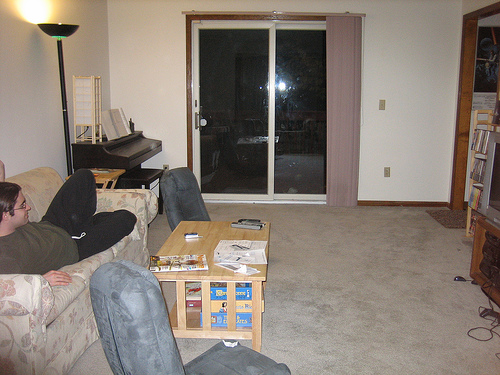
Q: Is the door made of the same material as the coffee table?
A: No, the door is made of glass and the coffee table is made of wood.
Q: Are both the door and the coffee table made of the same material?
A: No, the door is made of glass and the coffee table is made of wood.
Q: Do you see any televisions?
A: Yes, there is a television.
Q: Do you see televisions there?
A: Yes, there is a television.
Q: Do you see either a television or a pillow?
A: Yes, there is a television.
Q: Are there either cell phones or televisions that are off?
A: Yes, the television is off.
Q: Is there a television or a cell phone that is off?
A: Yes, the television is off.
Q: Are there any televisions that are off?
A: Yes, there is a television that is off.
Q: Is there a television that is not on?
A: Yes, there is a television that is off.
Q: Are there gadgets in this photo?
A: No, there are no gadgets.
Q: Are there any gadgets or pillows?
A: No, there are no gadgets or pillows.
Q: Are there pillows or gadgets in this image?
A: No, there are no gadgets or pillows.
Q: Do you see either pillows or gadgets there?
A: No, there are no gadgets or pillows.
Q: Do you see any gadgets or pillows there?
A: No, there are no gadgets or pillows.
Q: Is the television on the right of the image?
A: Yes, the television is on the right of the image.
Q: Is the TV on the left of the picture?
A: No, the TV is on the right of the image.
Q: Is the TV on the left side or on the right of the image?
A: The TV is on the right of the image.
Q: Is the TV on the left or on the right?
A: The TV is on the right of the image.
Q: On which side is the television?
A: The television is on the right of the image.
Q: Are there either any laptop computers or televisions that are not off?
A: No, there is a television but it is off.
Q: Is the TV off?
A: Yes, the TV is off.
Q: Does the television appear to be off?
A: Yes, the television is off.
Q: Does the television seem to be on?
A: No, the television is off.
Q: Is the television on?
A: No, the television is off.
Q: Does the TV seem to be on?
A: No, the TV is off.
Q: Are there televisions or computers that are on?
A: No, there is a television but it is off.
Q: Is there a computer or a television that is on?
A: No, there is a television but it is off.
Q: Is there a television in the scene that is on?
A: No, there is a television but it is off.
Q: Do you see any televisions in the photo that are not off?
A: No, there is a television but it is off.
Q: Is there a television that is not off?
A: No, there is a television but it is off.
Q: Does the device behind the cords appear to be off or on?
A: The TV is off.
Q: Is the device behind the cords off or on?
A: The TV is off.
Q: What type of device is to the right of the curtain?
A: The device is a television.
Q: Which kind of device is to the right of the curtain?
A: The device is a television.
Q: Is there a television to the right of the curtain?
A: Yes, there is a television to the right of the curtain.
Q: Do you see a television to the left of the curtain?
A: No, the television is to the right of the curtain.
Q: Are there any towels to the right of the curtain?
A: No, there is a television to the right of the curtain.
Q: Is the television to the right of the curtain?
A: Yes, the television is to the right of the curtain.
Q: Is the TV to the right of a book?
A: No, the TV is to the right of the curtain.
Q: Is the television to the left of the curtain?
A: No, the television is to the right of the curtain.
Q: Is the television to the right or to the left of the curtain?
A: The television is to the right of the curtain.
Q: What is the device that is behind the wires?
A: The device is a television.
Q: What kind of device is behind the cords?
A: The device is a television.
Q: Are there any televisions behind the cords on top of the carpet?
A: Yes, there is a television behind the wires.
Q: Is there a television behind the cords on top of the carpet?
A: Yes, there is a television behind the wires.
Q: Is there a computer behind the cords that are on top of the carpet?
A: No, there is a television behind the cords.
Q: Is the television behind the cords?
A: Yes, the television is behind the cords.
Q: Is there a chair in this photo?
A: Yes, there is a chair.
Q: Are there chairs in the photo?
A: Yes, there is a chair.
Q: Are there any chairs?
A: Yes, there is a chair.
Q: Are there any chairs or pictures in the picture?
A: Yes, there is a chair.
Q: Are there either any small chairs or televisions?
A: Yes, there is a small chair.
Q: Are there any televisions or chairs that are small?
A: Yes, the chair is small.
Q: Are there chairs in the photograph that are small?
A: Yes, there is a small chair.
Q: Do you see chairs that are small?
A: Yes, there is a chair that is small.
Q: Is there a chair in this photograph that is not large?
A: Yes, there is a small chair.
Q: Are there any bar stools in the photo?
A: No, there are no bar stools.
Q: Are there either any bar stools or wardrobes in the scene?
A: No, there are no bar stools or wardrobes.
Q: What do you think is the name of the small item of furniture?
A: The piece of furniture is a chair.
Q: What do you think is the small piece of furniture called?
A: The piece of furniture is a chair.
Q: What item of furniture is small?
A: The piece of furniture is a chair.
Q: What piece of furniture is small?
A: The piece of furniture is a chair.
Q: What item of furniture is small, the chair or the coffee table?
A: The chair is small.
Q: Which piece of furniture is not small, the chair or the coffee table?
A: The coffee table is not small.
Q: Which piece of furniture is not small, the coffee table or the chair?
A: The coffee table is not small.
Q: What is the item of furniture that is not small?
A: The piece of furniture is a coffee table.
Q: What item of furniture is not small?
A: The piece of furniture is a coffee table.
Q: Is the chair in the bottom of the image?
A: Yes, the chair is in the bottom of the image.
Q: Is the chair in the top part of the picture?
A: No, the chair is in the bottom of the image.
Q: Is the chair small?
A: Yes, the chair is small.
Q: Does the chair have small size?
A: Yes, the chair is small.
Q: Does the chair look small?
A: Yes, the chair is small.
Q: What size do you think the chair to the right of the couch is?
A: The chair is small.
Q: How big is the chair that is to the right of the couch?
A: The chair is small.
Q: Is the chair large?
A: No, the chair is small.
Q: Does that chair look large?
A: No, the chair is small.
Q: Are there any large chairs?
A: No, there is a chair but it is small.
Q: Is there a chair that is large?
A: No, there is a chair but it is small.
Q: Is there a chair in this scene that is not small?
A: No, there is a chair but it is small.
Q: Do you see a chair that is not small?
A: No, there is a chair but it is small.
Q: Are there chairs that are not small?
A: No, there is a chair but it is small.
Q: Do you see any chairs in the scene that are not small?
A: No, there is a chair but it is small.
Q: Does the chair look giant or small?
A: The chair is small.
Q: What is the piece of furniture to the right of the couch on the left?
A: The piece of furniture is a chair.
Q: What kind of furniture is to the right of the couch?
A: The piece of furniture is a chair.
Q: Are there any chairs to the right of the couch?
A: Yes, there is a chair to the right of the couch.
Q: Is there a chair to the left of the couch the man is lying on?
A: No, the chair is to the right of the couch.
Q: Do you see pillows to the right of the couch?
A: No, there is a chair to the right of the couch.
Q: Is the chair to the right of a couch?
A: Yes, the chair is to the right of a couch.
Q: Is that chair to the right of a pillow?
A: No, the chair is to the right of a couch.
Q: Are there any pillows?
A: No, there are no pillows.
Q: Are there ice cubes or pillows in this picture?
A: No, there are no pillows or ice cubes.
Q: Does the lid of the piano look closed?
A: Yes, the lid is closed.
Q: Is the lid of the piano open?
A: No, the lid is closed.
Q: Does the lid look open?
A: No, the lid is closed.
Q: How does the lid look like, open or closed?
A: The lid is closed.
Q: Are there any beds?
A: No, there are no beds.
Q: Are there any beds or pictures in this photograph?
A: No, there are no beds or pictures.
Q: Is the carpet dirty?
A: Yes, the carpet is dirty.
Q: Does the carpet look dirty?
A: Yes, the carpet is dirty.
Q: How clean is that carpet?
A: The carpet is dirty.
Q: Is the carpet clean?
A: No, the carpet is dirty.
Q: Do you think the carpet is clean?
A: No, the carpet is dirty.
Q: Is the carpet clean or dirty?
A: The carpet is dirty.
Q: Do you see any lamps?
A: Yes, there is a lamp.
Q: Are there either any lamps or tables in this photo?
A: Yes, there is a lamp.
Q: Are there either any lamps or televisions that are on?
A: Yes, the lamp is on.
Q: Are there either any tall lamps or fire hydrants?
A: Yes, there is a tall lamp.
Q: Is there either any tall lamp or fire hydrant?
A: Yes, there is a tall lamp.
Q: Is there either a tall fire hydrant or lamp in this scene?
A: Yes, there is a tall lamp.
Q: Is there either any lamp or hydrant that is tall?
A: Yes, the lamp is tall.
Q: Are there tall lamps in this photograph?
A: Yes, there is a tall lamp.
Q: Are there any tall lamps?
A: Yes, there is a tall lamp.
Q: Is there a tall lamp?
A: Yes, there is a tall lamp.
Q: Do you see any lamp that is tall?
A: Yes, there is a tall lamp.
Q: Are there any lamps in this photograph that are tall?
A: Yes, there is a lamp that is tall.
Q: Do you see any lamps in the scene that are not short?
A: Yes, there is a tall lamp.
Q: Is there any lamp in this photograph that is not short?
A: Yes, there is a tall lamp.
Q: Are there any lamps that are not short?
A: Yes, there is a tall lamp.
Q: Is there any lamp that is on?
A: Yes, there is a lamp that is on.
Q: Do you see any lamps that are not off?
A: Yes, there is a lamp that is on .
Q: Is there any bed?
A: No, there are no beds.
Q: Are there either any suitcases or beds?
A: No, there are no beds or suitcases.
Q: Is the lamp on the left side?
A: Yes, the lamp is on the left of the image.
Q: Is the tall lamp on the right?
A: No, the lamp is on the left of the image.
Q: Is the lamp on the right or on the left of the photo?
A: The lamp is on the left of the image.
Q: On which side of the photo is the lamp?
A: The lamp is on the left of the image.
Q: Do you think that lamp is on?
A: Yes, the lamp is on.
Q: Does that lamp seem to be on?
A: Yes, the lamp is on.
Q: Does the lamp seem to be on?
A: Yes, the lamp is on.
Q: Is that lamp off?
A: No, the lamp is on.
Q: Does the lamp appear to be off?
A: No, the lamp is on.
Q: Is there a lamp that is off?
A: No, there is a lamp but it is on.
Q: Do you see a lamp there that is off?
A: No, there is a lamp but it is on.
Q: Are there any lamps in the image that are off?
A: No, there is a lamp but it is on.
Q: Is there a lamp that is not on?
A: No, there is a lamp but it is on.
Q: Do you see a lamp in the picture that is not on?
A: No, there is a lamp but it is on.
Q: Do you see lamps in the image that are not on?
A: No, there is a lamp but it is on.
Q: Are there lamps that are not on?
A: No, there is a lamp but it is on.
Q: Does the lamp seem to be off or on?
A: The lamp is on.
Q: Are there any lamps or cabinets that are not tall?
A: No, there is a lamp but it is tall.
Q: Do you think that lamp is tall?
A: Yes, the lamp is tall.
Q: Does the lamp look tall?
A: Yes, the lamp is tall.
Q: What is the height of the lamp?
A: The lamp is tall.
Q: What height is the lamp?
A: The lamp is tall.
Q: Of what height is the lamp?
A: The lamp is tall.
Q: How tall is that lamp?
A: The lamp is tall.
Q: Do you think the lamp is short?
A: No, the lamp is tall.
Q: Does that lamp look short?
A: No, the lamp is tall.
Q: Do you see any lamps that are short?
A: No, there is a lamp but it is tall.